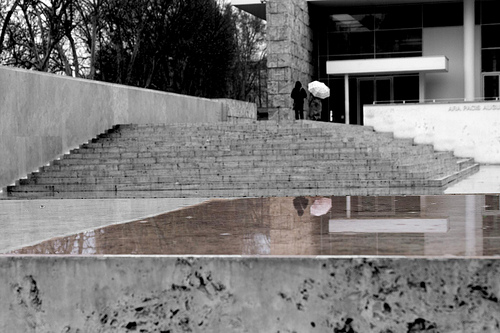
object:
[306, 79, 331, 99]
umbrella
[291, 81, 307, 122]
person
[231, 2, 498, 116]
building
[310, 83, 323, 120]
person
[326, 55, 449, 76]
awning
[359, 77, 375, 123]
door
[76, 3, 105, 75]
trees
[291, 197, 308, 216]
reflection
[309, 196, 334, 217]
reflection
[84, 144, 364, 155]
steps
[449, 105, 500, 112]
name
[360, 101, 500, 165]
wall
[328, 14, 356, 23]
lights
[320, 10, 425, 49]
ceiling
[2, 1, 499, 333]
photo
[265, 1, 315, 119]
column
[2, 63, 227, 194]
wall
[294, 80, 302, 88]
head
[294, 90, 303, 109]
black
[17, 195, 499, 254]
tile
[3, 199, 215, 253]
tile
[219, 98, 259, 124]
wall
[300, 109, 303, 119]
leg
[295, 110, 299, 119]
leg